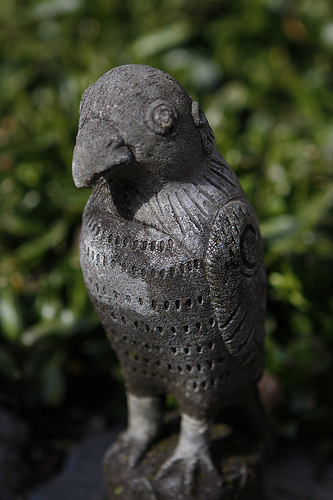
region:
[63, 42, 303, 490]
a statue of a bird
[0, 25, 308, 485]
a falcon made from an artist from stone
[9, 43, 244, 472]
a sculpture of a bird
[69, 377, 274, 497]
the feet of a bird made of stone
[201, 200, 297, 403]
the decorated stone falcon's wing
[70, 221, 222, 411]
the breast of the bird is decorated with hatch marks in rows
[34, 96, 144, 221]
falcon beak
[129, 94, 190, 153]
the falcon's eye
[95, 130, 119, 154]
the falcon's nostril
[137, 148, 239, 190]
the falcon's neck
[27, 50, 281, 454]
A stone bird statue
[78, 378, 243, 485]
The feet of a bird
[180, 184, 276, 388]
The wing of a bird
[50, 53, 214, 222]
The head of a bird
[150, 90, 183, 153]
The eye of a bird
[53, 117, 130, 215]
The beak of a bird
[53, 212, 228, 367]
The breast of a bird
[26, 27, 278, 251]
green leaves behind of a bird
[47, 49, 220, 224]
the head of a stone bird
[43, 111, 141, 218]
the beak of a stone bird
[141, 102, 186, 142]
the bird statues eye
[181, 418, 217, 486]
the bird statue foot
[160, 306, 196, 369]
holes in the grey statue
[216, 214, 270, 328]
the wing of the statue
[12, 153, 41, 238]
some green bushes in the backround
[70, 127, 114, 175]
the beak of the statue bird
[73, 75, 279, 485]
a grey statue of a bird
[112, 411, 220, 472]
this is the birds feet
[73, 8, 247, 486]
a silver looking statue of a bird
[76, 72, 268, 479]
this is a statue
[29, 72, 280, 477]
A stone bird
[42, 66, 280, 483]
A black stone bird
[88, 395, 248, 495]
The feet of a bird on a pedestool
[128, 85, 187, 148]
The eye of a bird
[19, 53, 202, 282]
Green leaves behind a bird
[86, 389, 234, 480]
The feet of a stone bird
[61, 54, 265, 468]
The sculpture is tall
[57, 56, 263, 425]
The sculpture is black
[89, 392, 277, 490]
The sculpture has a black base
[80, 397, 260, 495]
The base is small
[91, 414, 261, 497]
The base is round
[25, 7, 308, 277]
There is foliage behind the statue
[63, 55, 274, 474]
The statue is made of stone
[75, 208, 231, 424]
The statue has etching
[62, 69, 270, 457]
The statue is a bird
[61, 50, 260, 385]
The bird statue is standing